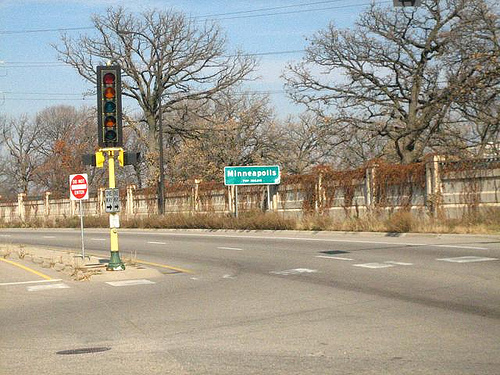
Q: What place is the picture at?
A: It is at the road.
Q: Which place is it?
A: It is a road.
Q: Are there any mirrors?
A: No, there are no mirrors.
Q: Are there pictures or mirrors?
A: No, there are no mirrors or pictures.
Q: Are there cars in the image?
A: No, there are no cars.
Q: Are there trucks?
A: No, there are no trucks.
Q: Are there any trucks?
A: No, there are no trucks.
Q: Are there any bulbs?
A: No, there are no bulbs.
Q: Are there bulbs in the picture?
A: No, there are no bulbs.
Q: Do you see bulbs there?
A: No, there are no bulbs.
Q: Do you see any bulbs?
A: No, there are no bulbs.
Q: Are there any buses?
A: No, there are no buses.